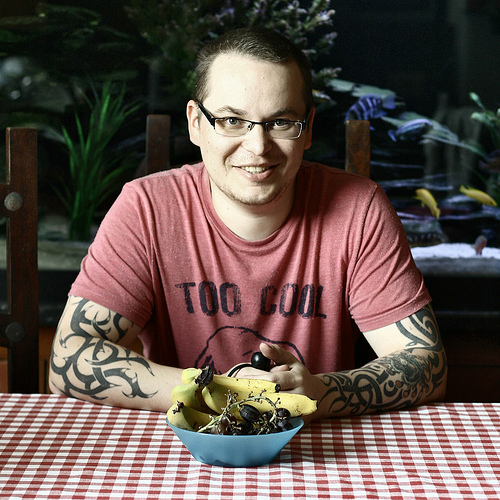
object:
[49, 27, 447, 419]
man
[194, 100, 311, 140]
glasses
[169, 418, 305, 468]
bowl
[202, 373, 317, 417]
bananas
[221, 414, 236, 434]
grapes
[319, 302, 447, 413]
tattoos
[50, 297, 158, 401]
tattoos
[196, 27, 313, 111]
hair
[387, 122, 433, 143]
fish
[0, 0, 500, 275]
aquarium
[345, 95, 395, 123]
fish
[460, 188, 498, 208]
fish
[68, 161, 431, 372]
shirt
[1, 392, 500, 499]
table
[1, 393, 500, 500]
tablecloth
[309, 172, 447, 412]
arm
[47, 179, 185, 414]
arm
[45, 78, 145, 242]
plant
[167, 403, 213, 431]
fruit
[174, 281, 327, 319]
too cool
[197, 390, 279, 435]
stem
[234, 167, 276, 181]
lips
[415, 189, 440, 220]
fish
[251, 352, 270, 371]
object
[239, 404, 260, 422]
grape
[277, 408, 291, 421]
grape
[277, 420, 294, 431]
grape